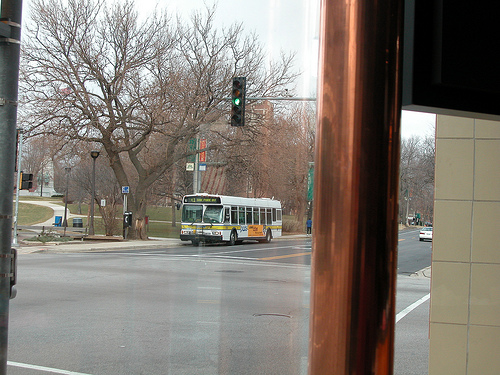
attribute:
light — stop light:
[178, 229, 193, 235]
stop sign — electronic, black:
[229, 74, 246, 129]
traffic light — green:
[229, 75, 246, 131]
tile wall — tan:
[434, 116, 498, 373]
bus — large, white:
[179, 193, 283, 248]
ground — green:
[461, 126, 492, 174]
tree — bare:
[16, 0, 301, 240]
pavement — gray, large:
[5, 215, 435, 374]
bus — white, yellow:
[176, 187, 286, 250]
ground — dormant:
[406, 171, 464, 231]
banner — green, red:
[177, 129, 214, 173]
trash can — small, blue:
[51, 215, 63, 227]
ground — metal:
[391, 201, 421, 237]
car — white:
[417, 225, 433, 242]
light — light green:
[229, 77, 246, 127]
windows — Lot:
[223, 203, 282, 224]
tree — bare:
[26, 7, 238, 253]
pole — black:
[86, 157, 95, 237]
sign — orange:
[241, 225, 271, 241]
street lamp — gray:
[86, 140, 159, 241]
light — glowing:
[218, 69, 256, 140]